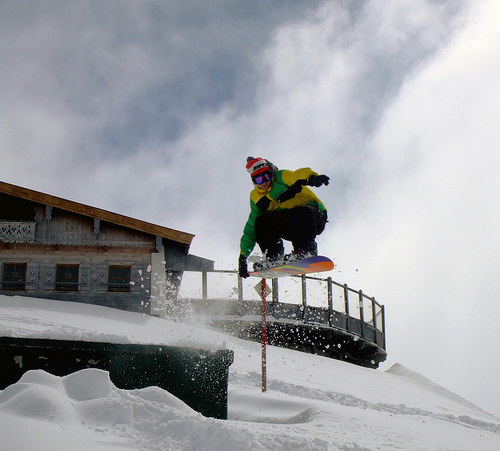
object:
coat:
[237, 166, 321, 262]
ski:
[0, 282, 236, 435]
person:
[236, 156, 330, 280]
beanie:
[241, 152, 268, 173]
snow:
[0, 295, 499, 449]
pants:
[255, 207, 327, 261]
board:
[248, 255, 333, 278]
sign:
[251, 275, 271, 391]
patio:
[168, 259, 385, 370]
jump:
[0, 332, 233, 429]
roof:
[0, 180, 195, 247]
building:
[0, 177, 389, 371]